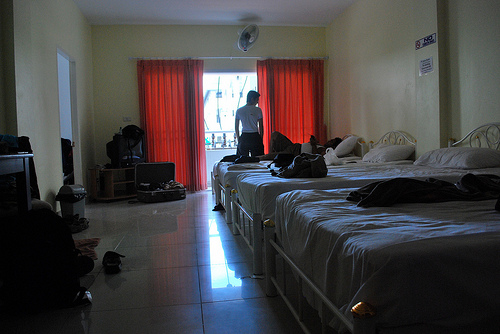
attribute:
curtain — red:
[136, 59, 202, 190]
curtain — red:
[258, 60, 326, 155]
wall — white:
[327, 1, 500, 147]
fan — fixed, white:
[235, 23, 259, 52]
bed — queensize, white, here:
[277, 188, 499, 333]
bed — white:
[235, 165, 500, 217]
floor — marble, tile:
[92, 190, 281, 334]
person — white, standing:
[233, 90, 265, 157]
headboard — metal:
[446, 120, 498, 151]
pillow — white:
[360, 145, 415, 164]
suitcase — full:
[137, 163, 185, 201]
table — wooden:
[1, 153, 35, 209]